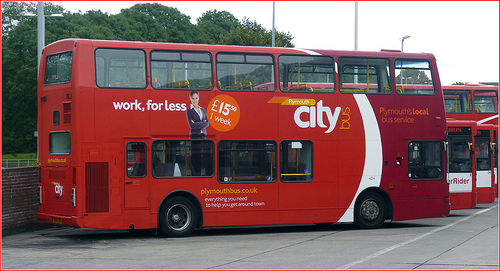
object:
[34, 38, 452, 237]
bus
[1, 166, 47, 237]
wall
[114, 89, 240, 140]
advertisement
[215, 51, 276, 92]
window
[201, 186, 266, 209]
lettering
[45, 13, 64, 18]
light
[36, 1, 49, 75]
pole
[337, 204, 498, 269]
line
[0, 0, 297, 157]
tree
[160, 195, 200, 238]
tire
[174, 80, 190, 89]
seat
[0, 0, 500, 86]
sky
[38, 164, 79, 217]
engine